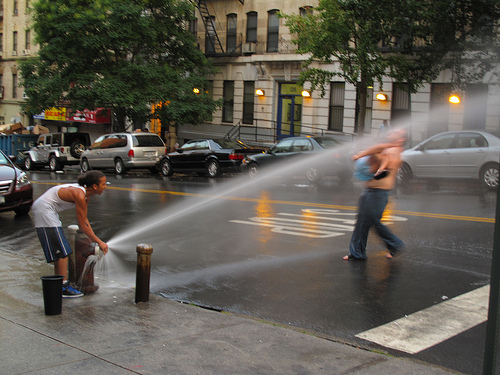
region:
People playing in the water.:
[43, 119, 437, 291]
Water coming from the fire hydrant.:
[62, 211, 138, 304]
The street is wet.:
[163, 178, 429, 303]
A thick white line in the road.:
[366, 288, 492, 349]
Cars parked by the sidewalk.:
[96, 121, 348, 194]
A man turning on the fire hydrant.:
[27, 161, 128, 295]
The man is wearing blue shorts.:
[16, 218, 91, 263]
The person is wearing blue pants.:
[328, 183, 417, 275]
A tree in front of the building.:
[46, 14, 243, 131]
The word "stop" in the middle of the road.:
[238, 213, 388, 252]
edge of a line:
[370, 317, 384, 327]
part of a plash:
[246, 156, 308, 244]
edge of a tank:
[129, 235, 151, 261]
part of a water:
[192, 233, 244, 293]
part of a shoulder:
[73, 197, 90, 213]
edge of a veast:
[31, 216, 63, 231]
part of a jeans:
[372, 217, 399, 263]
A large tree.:
[25, 6, 220, 132]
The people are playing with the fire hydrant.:
[25, 110, 440, 305]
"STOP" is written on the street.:
[225, 187, 412, 248]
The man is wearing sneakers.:
[47, 270, 94, 301]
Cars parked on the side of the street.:
[30, 115, 495, 200]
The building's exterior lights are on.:
[185, 75, 480, 120]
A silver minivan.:
[75, 125, 166, 180]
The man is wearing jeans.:
[342, 180, 402, 260]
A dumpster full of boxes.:
[0, 115, 50, 156]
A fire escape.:
[177, 0, 253, 61]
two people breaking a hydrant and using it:
[20, 102, 498, 349]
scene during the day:
[0, 0, 480, 370]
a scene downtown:
[5, 0, 495, 360]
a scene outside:
[10, 25, 495, 350]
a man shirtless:
[330, 113, 432, 315]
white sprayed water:
[107, 101, 496, 340]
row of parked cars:
[25, 112, 496, 214]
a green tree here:
[13, 20, 238, 141]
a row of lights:
[160, 60, 496, 120]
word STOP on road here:
[235, 194, 428, 253]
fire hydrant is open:
[51, 216, 153, 296]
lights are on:
[191, 74, 494, 108]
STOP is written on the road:
[236, 195, 418, 265]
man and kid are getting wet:
[341, 126, 451, 268]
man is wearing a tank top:
[40, 175, 86, 241]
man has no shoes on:
[332, 247, 419, 286]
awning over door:
[33, 91, 130, 138]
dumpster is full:
[4, 117, 54, 159]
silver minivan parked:
[80, 112, 177, 188]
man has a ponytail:
[59, 160, 118, 203]